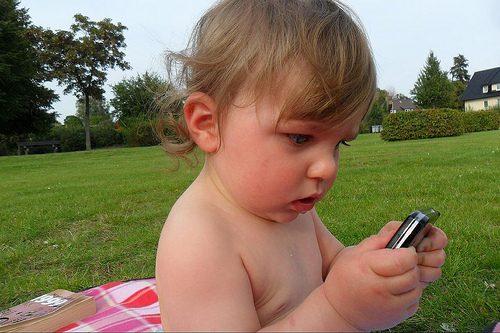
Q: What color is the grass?
A: Green.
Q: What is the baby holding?
A: A cellphone.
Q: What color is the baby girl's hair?
A: Blonde.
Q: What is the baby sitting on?
A: A blanket.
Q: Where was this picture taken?
A: A backyard.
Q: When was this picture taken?
A: Daytime.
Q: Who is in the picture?
A: A baby girl.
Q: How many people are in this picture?
A: One.